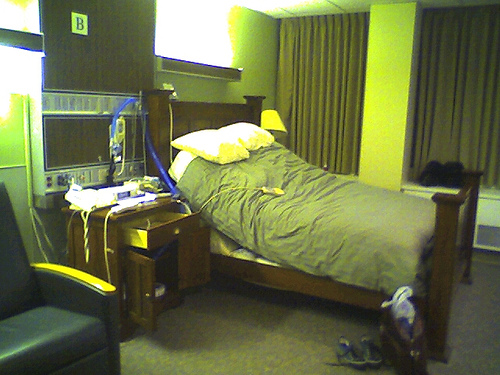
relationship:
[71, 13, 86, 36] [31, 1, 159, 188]
b on wall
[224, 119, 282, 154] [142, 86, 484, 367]
left pillow on bed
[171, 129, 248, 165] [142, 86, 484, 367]
pillows on bed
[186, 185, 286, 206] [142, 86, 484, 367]
remote on bed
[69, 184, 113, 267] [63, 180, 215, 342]
phone on desk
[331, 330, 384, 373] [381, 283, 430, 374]
shoes are next to bag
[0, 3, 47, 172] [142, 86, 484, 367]
lamp next to bed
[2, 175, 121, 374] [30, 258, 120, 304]
chair has an arm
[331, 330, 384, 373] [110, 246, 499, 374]
shoes are on floor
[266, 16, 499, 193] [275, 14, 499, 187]
curtain on window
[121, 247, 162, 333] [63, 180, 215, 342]
door on nightstand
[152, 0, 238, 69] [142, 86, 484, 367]
light above bed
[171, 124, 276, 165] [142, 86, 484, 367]
pillows are on bed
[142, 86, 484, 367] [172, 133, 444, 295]
bed comes with sheets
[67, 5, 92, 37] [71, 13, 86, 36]
label has b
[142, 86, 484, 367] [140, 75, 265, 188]
hospital bed has a headboard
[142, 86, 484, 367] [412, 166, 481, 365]
bed has a footboard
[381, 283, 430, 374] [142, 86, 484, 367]
bag sitting beside bed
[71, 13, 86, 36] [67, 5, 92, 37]
b in white square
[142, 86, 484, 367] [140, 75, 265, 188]
bed has wooden frame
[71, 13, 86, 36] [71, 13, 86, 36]
b says b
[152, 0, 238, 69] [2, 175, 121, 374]
light above chair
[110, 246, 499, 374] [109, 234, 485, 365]
carpet on floor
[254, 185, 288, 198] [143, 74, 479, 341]
remote unit for bed